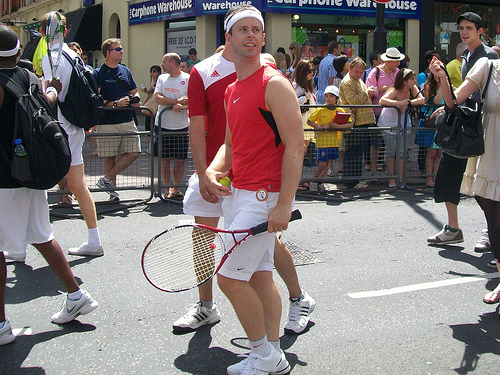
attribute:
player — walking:
[204, 6, 307, 374]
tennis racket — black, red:
[142, 209, 303, 294]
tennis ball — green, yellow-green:
[218, 176, 232, 189]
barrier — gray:
[297, 102, 445, 188]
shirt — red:
[226, 65, 288, 192]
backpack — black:
[0, 67, 73, 189]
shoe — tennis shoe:
[239, 344, 287, 374]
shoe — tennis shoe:
[227, 354, 247, 374]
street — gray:
[0, 180, 499, 374]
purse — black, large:
[433, 60, 493, 157]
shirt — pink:
[364, 65, 405, 116]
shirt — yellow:
[307, 103, 352, 146]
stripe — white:
[346, 271, 500, 299]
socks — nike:
[246, 335, 282, 356]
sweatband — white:
[222, 9, 264, 34]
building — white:
[101, 1, 419, 124]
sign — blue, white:
[128, 2, 418, 25]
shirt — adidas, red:
[189, 51, 239, 168]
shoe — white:
[68, 241, 104, 258]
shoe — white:
[49, 292, 98, 323]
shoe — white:
[2, 321, 15, 347]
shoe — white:
[284, 292, 316, 333]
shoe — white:
[171, 304, 222, 330]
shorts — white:
[219, 186, 288, 282]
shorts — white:
[1, 188, 56, 261]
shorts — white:
[64, 127, 86, 166]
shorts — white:
[181, 173, 222, 218]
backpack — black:
[51, 47, 104, 129]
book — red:
[332, 112, 351, 122]